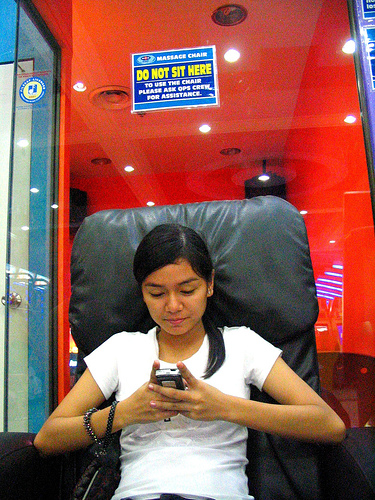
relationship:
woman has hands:
[29, 216, 368, 499] [130, 356, 218, 426]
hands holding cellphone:
[130, 356, 218, 426] [153, 367, 185, 396]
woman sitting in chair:
[29, 216, 368, 499] [0, 193, 373, 500]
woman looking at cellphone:
[29, 216, 368, 499] [153, 367, 185, 396]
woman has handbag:
[29, 216, 368, 499] [66, 400, 119, 499]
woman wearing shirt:
[29, 216, 368, 499] [71, 323, 285, 500]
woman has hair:
[29, 216, 368, 499] [129, 216, 230, 382]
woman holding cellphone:
[29, 216, 368, 499] [153, 367, 185, 396]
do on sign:
[130, 68, 151, 83] [123, 42, 231, 121]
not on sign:
[150, 65, 171, 81] [123, 42, 231, 121]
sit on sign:
[168, 63, 188, 80] [123, 42, 231, 121]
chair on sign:
[178, 75, 207, 87] [123, 42, 231, 121]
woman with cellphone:
[29, 216, 368, 499] [153, 367, 185, 396]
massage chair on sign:
[150, 50, 216, 63] [123, 42, 231, 121]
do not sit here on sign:
[131, 60, 213, 85] [123, 42, 231, 121]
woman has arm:
[29, 216, 368, 499] [29, 358, 171, 459]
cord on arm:
[82, 401, 120, 453] [29, 358, 171, 459]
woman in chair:
[29, 216, 368, 499] [0, 193, 373, 500]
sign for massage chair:
[123, 42, 231, 121] [150, 50, 216, 63]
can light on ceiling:
[218, 47, 245, 68] [73, 2, 322, 177]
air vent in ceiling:
[85, 82, 142, 121] [73, 2, 322, 177]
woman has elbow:
[29, 216, 368, 499] [321, 410, 355, 448]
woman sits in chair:
[29, 216, 368, 499] [0, 193, 373, 500]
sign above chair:
[123, 42, 231, 121] [0, 193, 373, 500]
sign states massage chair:
[123, 42, 231, 121] [150, 50, 216, 63]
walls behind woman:
[28, 0, 373, 353] [29, 216, 368, 499]